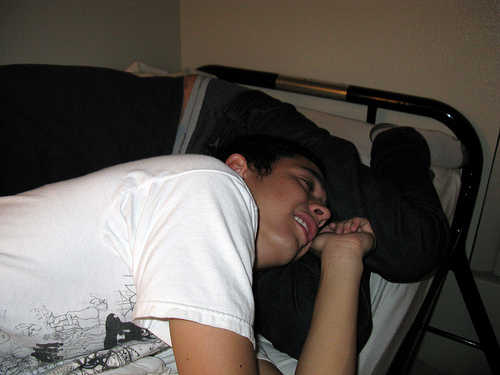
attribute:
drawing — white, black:
[21, 300, 143, 372]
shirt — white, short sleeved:
[3, 154, 250, 334]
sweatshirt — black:
[0, 59, 187, 201]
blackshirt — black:
[3, 61, 158, 152]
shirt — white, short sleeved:
[2, 152, 276, 371]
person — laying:
[0, 142, 376, 374]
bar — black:
[196, 63, 483, 230]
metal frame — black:
[198, 60, 498, 370]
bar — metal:
[194, 62, 499, 374]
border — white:
[166, 72, 216, 152]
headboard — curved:
[206, 64, 479, 179]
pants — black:
[202, 90, 454, 356]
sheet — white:
[286, 100, 464, 373]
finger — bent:
[324, 222, 337, 232]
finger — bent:
[337, 221, 344, 236]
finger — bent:
[342, 220, 352, 232]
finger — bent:
[347, 216, 369, 234]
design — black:
[2, 285, 171, 371]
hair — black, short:
[214, 130, 329, 175]